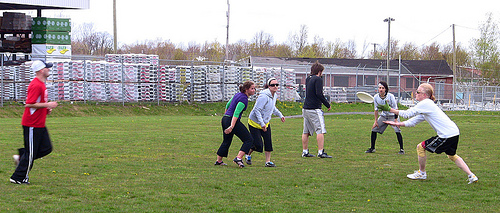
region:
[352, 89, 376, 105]
A white frisbee.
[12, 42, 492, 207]
People playing ultimate frisbee.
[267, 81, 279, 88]
A pair of black sunglasses.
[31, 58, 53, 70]
A white and black ball cap.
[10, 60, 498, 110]
A grey chain linked fence.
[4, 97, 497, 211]
The green grass.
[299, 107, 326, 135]
Silver and white sport shorts.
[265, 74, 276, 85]
A white headband.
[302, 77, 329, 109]
A long sleeved black shirt.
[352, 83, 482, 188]
A girl about to catch a frisbee.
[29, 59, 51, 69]
a white ball cap with black bill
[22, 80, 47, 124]
a red short sleeve shirt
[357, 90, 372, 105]
a white color frisbee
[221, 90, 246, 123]
a green long sleeve shirt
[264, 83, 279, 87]
a dark pair of sunglasses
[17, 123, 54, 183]
a black pair of sports pants with white stripe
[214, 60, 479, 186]
group of people playing with frisbee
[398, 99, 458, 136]
white long sleeve shirt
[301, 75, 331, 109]
a dark long sleeve shirt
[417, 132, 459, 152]
a pair of black basketball shorts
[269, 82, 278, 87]
Dark shades covering the eyes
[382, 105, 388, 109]
A glove in the hand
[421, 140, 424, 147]
A patch of red on shorts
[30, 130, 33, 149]
White stripes on slacks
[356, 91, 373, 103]
A white fresbie in the air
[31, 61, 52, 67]
A white and black cap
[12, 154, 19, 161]
Shoe up in the air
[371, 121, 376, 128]
Hand holding the knee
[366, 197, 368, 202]
A yellow spot in the grass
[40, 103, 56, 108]
Arm held to the side of the body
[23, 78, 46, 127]
a red short sleeve shirt with whtie sides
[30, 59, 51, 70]
a white ball cap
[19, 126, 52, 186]
black workout pnts with white stripe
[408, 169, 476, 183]
a pair of white tennis shoes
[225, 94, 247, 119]
blue short sleeve shirt with green long sleeve undershirt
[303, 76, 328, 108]
dark long sleeve shirt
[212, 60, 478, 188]
group of people playing frisbee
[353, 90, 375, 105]
a white frisbee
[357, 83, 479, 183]
person catching frisbee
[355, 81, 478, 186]
girl about to catch a frisbee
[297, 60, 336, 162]
man in grey and white shorts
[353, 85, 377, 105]
white frisbee mid air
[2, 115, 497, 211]
green grass on field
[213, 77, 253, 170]
girl with a ponytail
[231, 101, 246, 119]
long greensleeve on arm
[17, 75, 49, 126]
red short sleeve shirt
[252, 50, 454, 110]
red brick building behind fence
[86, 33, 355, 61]
brown and green leaves on trees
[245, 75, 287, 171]
girl with grey hooded sweatshirt